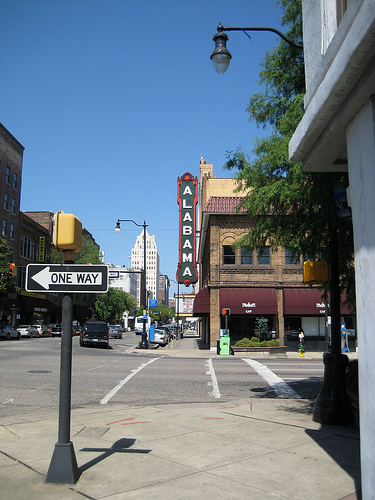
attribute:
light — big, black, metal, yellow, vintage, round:
[211, 23, 234, 68]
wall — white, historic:
[279, 0, 373, 497]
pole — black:
[45, 299, 81, 482]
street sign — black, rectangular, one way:
[23, 262, 107, 291]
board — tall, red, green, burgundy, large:
[175, 172, 202, 287]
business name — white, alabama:
[179, 180, 193, 281]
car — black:
[78, 316, 112, 348]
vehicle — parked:
[140, 330, 171, 350]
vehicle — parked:
[10, 320, 39, 345]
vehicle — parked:
[29, 325, 51, 337]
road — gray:
[0, 316, 351, 414]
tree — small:
[228, 4, 370, 269]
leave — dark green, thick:
[233, 0, 357, 267]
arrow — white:
[29, 266, 104, 289]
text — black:
[49, 271, 101, 290]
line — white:
[200, 353, 225, 404]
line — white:
[244, 358, 297, 397]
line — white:
[104, 353, 162, 402]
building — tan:
[194, 161, 370, 348]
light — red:
[74, 328, 84, 344]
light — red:
[104, 331, 111, 345]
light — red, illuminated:
[220, 306, 230, 323]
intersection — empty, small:
[37, 342, 200, 405]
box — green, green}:
[211, 331, 234, 356]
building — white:
[133, 227, 172, 320]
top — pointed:
[132, 224, 157, 240]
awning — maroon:
[192, 289, 353, 319]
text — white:
[239, 295, 259, 319]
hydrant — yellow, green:
[290, 331, 314, 358]